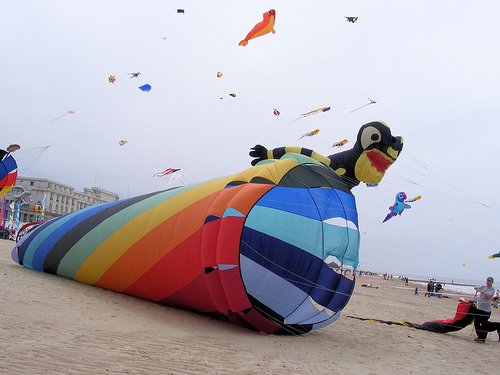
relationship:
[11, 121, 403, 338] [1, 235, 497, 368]
kite on ground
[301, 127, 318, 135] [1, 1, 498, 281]
kite in sky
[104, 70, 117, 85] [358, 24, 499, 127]
kite in sky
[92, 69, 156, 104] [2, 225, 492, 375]
kites at beach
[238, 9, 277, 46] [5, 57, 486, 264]
kite in sky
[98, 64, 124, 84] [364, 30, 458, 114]
kite in sky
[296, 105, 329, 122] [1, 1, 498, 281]
kite in sky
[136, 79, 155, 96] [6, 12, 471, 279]
kite in sky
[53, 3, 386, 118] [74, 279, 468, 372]
kites on beach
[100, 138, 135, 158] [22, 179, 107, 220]
kite by building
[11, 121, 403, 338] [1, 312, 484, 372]
kite on beach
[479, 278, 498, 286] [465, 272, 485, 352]
hat on man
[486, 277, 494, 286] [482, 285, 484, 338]
hat on man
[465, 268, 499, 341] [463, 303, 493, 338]
man with pants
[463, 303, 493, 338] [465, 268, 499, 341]
pants on man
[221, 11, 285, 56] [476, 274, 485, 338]
kite with man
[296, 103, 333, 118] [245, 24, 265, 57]
kites with tails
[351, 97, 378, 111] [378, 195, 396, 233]
kites with tails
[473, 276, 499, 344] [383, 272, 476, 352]
man with kite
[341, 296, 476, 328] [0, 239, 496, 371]
kite on sand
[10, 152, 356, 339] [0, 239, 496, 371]
kite on sand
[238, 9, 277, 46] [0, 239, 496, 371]
kite on sand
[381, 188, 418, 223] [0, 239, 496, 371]
kite on sand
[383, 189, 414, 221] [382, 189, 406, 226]
kite shaped bird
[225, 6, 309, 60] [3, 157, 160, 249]
building in distance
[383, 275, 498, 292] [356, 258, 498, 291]
ocean in background